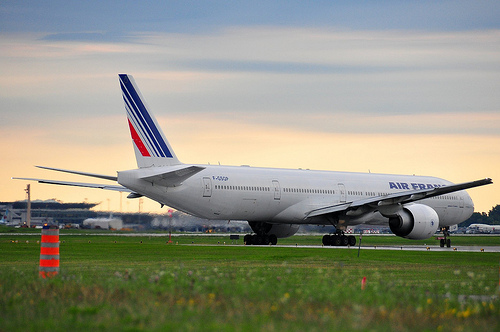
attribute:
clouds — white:
[281, 13, 493, 157]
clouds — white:
[184, 18, 495, 82]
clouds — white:
[410, 99, 463, 124]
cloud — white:
[71, 45, 124, 56]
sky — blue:
[6, 0, 499, 230]